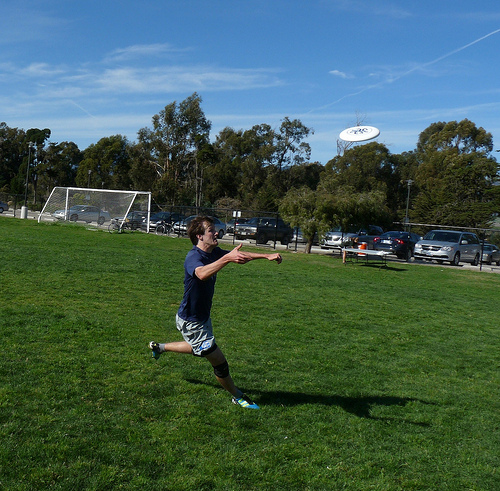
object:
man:
[149, 215, 283, 409]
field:
[0, 213, 499, 490]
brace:
[213, 360, 231, 378]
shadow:
[186, 384, 451, 423]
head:
[184, 217, 220, 248]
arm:
[184, 254, 230, 279]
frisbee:
[337, 124, 383, 140]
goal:
[37, 184, 154, 230]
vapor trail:
[298, 30, 498, 115]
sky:
[0, 0, 499, 170]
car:
[370, 232, 416, 258]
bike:
[154, 218, 175, 237]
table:
[339, 247, 390, 264]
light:
[403, 176, 413, 191]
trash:
[20, 204, 28, 221]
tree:
[316, 139, 398, 246]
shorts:
[171, 311, 217, 356]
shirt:
[175, 246, 230, 322]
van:
[411, 229, 483, 267]